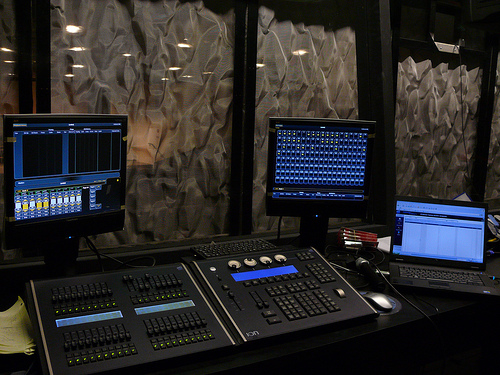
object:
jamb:
[233, 2, 256, 234]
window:
[39, 4, 251, 246]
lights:
[287, 45, 308, 57]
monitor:
[387, 194, 491, 266]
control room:
[7, 8, 495, 368]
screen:
[264, 117, 385, 216]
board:
[21, 260, 235, 372]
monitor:
[0, 113, 127, 262]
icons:
[9, 174, 112, 219]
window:
[386, 30, 486, 236]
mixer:
[31, 236, 374, 371]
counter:
[30, 240, 374, 372]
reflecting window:
[133, 7, 253, 166]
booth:
[2, 114, 499, 373]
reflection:
[178, 42, 190, 48]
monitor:
[33, 261, 243, 370]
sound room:
[2, 2, 495, 373]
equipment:
[14, 242, 391, 372]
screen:
[11, 119, 122, 215]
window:
[253, 10, 368, 236]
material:
[48, 0, 236, 247]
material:
[255, 5, 358, 236]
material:
[391, 47, 481, 227]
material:
[483, 51, 499, 213]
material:
[1, 2, 21, 144]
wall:
[1, 1, 499, 264]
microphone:
[322, 240, 387, 287]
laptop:
[385, 194, 492, 300]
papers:
[3, 296, 29, 354]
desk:
[0, 208, 500, 358]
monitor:
[263, 111, 380, 216]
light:
[174, 38, 194, 50]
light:
[61, 23, 86, 36]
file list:
[401, 217, 484, 259]